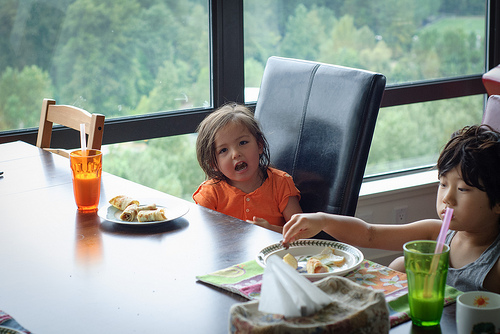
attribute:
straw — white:
[78, 128, 93, 182]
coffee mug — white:
[452, 287, 499, 332]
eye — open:
[236, 137, 251, 150]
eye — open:
[216, 145, 231, 155]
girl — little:
[186, 102, 311, 234]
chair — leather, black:
[210, 36, 410, 254]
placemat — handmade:
[187, 271, 269, 294]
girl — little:
[178, 99, 313, 251]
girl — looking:
[190, 97, 280, 201]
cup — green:
[400, 237, 454, 327]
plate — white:
[94, 190, 191, 225]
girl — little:
[171, 110, 294, 233]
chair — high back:
[242, 32, 397, 229]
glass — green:
[366, 228, 459, 316]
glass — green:
[401, 237, 449, 329]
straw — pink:
[424, 205, 454, 300]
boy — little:
[283, 124, 499, 291]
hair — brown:
[193, 97, 273, 184]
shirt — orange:
[184, 171, 298, 237]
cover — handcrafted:
[219, 262, 400, 327]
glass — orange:
[64, 142, 105, 218]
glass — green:
[395, 224, 456, 329]